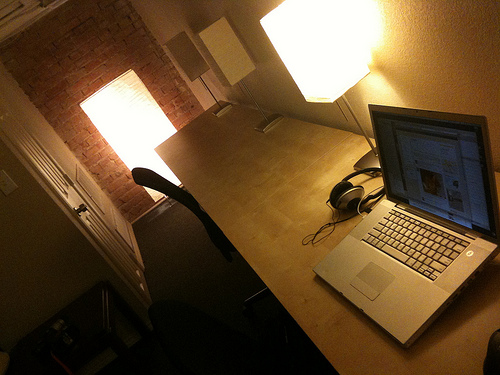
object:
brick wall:
[0, 0, 202, 222]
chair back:
[132, 167, 244, 264]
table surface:
[153, 100, 500, 375]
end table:
[0, 284, 143, 374]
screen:
[371, 112, 490, 231]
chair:
[131, 167, 248, 267]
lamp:
[162, 31, 231, 117]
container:
[53, 317, 74, 344]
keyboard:
[364, 208, 471, 281]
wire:
[301, 185, 384, 245]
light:
[188, 16, 256, 87]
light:
[162, 30, 210, 82]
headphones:
[330, 167, 386, 210]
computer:
[313, 104, 500, 349]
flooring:
[130, 204, 332, 375]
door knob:
[73, 203, 87, 216]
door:
[0, 110, 152, 309]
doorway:
[80, 70, 180, 202]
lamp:
[192, 17, 284, 133]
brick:
[0, 0, 204, 222]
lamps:
[258, 0, 383, 176]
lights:
[258, 0, 369, 106]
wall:
[0, 0, 500, 375]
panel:
[79, 68, 131, 106]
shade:
[164, 30, 210, 82]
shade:
[187, 14, 259, 66]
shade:
[257, 0, 372, 104]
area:
[0, 281, 155, 371]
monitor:
[372, 112, 491, 231]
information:
[377, 118, 490, 228]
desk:
[153, 100, 500, 375]